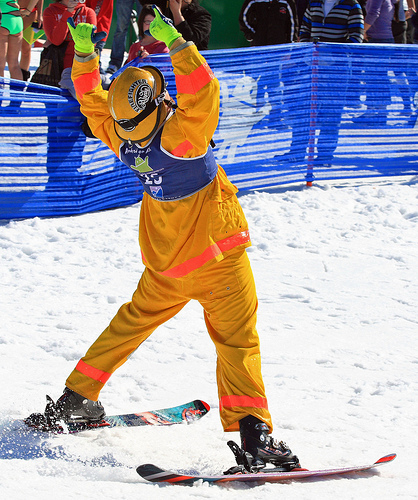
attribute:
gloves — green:
[138, 13, 181, 47]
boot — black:
[56, 387, 105, 425]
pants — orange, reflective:
[64, 250, 271, 430]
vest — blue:
[120, 111, 217, 202]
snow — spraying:
[53, 447, 104, 465]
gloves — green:
[148, 15, 179, 44]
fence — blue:
[221, 29, 395, 202]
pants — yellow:
[65, 231, 271, 410]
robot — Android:
[128, 150, 157, 174]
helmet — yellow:
[100, 60, 165, 147]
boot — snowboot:
[53, 371, 318, 471]